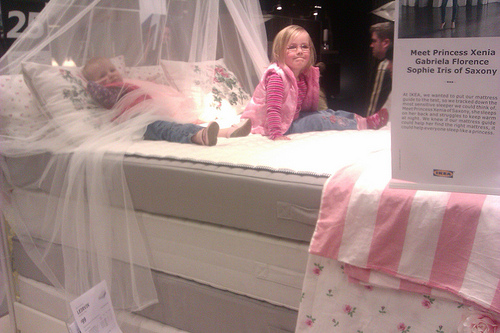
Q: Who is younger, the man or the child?
A: The child is younger than the man.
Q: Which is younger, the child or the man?
A: The child is younger than the man.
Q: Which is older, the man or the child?
A: The man is older than the child.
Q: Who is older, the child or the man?
A: The man is older than the child.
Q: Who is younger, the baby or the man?
A: The baby is younger than the man.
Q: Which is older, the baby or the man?
A: The man is older than the baby.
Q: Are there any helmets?
A: No, there are no helmets.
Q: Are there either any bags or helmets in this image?
A: No, there are no helmets or bags.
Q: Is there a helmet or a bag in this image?
A: No, there are no helmets or bags.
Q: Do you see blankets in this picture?
A: Yes, there is a blanket.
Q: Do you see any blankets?
A: Yes, there is a blanket.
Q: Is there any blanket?
A: Yes, there is a blanket.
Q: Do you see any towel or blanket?
A: Yes, there is a blanket.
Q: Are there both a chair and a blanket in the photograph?
A: No, there is a blanket but no chairs.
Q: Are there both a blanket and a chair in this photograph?
A: No, there is a blanket but no chairs.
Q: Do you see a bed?
A: Yes, there is a bed.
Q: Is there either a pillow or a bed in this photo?
A: Yes, there is a bed.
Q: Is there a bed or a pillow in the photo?
A: Yes, there is a bed.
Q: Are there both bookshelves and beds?
A: No, there is a bed but no bookshelves.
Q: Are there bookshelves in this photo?
A: No, there are no bookshelves.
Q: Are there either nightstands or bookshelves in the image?
A: No, there are no bookshelves or nightstands.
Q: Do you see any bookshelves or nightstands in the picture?
A: No, there are no bookshelves or nightstands.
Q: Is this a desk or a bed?
A: This is a bed.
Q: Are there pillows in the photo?
A: Yes, there is a pillow.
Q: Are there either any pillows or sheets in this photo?
A: Yes, there is a pillow.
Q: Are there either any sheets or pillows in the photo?
A: Yes, there is a pillow.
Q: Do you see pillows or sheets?
A: Yes, there is a pillow.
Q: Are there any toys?
A: No, there are no toys.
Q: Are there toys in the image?
A: No, there are no toys.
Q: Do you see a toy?
A: No, there are no toys.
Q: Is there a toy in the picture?
A: No, there are no toys.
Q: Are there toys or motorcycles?
A: No, there are no toys or motorcycles.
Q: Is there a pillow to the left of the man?
A: Yes, there is a pillow to the left of the man.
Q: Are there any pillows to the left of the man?
A: Yes, there is a pillow to the left of the man.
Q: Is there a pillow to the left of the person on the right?
A: Yes, there is a pillow to the left of the man.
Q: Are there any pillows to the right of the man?
A: No, the pillow is to the left of the man.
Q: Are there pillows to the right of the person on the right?
A: No, the pillow is to the left of the man.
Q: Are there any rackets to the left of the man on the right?
A: No, there is a pillow to the left of the man.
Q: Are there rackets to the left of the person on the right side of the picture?
A: No, there is a pillow to the left of the man.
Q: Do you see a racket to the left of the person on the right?
A: No, there is a pillow to the left of the man.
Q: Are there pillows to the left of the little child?
A: Yes, there is a pillow to the left of the child.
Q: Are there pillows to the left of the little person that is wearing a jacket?
A: Yes, there is a pillow to the left of the child.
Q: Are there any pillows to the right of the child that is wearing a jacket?
A: No, the pillow is to the left of the kid.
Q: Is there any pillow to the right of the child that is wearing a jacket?
A: No, the pillow is to the left of the kid.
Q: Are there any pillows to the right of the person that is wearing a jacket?
A: No, the pillow is to the left of the kid.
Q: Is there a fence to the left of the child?
A: No, there is a pillow to the left of the child.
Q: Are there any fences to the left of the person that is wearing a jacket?
A: No, there is a pillow to the left of the child.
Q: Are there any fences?
A: No, there are no fences.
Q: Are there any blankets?
A: Yes, there is a blanket.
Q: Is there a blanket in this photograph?
A: Yes, there is a blanket.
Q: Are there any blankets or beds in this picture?
A: Yes, there is a blanket.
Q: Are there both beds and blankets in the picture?
A: Yes, there are both a blanket and a bed.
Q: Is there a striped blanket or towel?
A: Yes, there is a striped blanket.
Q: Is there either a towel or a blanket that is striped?
A: Yes, the blanket is striped.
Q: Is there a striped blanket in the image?
A: Yes, there is a striped blanket.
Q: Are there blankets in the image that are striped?
A: Yes, there is a blanket that is striped.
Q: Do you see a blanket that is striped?
A: Yes, there is a blanket that is striped.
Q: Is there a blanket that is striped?
A: Yes, there is a blanket that is striped.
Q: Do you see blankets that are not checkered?
A: Yes, there is a striped blanket.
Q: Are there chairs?
A: No, there are no chairs.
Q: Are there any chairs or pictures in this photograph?
A: No, there are no chairs or pictures.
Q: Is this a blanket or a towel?
A: This is a blanket.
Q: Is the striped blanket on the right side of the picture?
A: Yes, the blanket is on the right of the image.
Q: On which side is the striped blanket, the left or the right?
A: The blanket is on the right of the image.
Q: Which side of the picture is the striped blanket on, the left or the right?
A: The blanket is on the right of the image.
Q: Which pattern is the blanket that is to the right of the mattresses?
A: The blanket is striped.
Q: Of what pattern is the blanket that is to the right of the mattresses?
A: The blanket is striped.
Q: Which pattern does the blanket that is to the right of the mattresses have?
A: The blanket has striped pattern.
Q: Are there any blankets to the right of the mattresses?
A: Yes, there is a blanket to the right of the mattresses.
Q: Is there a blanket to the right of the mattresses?
A: Yes, there is a blanket to the right of the mattresses.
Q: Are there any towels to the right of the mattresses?
A: No, there is a blanket to the right of the mattresses.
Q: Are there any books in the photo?
A: No, there are no books.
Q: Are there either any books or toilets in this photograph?
A: No, there are no books or toilets.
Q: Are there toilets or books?
A: No, there are no books or toilets.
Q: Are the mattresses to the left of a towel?
A: No, the mattresses are to the left of the blanket.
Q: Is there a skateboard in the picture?
A: No, there are no skateboards.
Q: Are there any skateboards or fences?
A: No, there are no skateboards or fences.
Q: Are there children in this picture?
A: Yes, there is a child.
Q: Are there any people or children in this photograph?
A: Yes, there is a child.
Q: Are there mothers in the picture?
A: No, there are no mothers.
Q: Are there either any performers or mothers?
A: No, there are no mothers or performers.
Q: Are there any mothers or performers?
A: No, there are no mothers or performers.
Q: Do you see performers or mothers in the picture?
A: No, there are no mothers or performers.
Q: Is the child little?
A: Yes, the child is little.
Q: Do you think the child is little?
A: Yes, the child is little.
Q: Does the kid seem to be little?
A: Yes, the kid is little.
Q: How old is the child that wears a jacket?
A: The child is little.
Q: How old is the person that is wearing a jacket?
A: The child is little.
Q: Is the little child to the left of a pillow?
A: No, the child is to the right of a pillow.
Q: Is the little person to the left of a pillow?
A: No, the child is to the right of a pillow.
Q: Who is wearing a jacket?
A: The child is wearing a jacket.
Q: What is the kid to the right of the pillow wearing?
A: The kid is wearing a jacket.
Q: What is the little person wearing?
A: The kid is wearing a jacket.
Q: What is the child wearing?
A: The kid is wearing a jacket.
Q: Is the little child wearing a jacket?
A: Yes, the child is wearing a jacket.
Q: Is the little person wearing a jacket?
A: Yes, the child is wearing a jacket.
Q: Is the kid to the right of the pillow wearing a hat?
A: No, the child is wearing a jacket.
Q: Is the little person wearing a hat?
A: No, the child is wearing a jacket.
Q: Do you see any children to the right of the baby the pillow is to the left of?
A: Yes, there is a child to the right of the baby.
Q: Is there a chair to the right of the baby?
A: No, there is a child to the right of the baby.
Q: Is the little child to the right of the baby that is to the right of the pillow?
A: Yes, the kid is to the right of the baby.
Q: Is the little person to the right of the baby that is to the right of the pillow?
A: Yes, the kid is to the right of the baby.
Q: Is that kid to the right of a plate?
A: No, the kid is to the right of the baby.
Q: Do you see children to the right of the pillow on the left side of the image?
A: Yes, there is a child to the right of the pillow.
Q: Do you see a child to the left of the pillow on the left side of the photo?
A: No, the child is to the right of the pillow.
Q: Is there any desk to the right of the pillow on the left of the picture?
A: No, there is a child to the right of the pillow.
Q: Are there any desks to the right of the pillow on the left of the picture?
A: No, there is a child to the right of the pillow.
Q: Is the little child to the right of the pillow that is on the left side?
A: Yes, the child is to the right of the pillow.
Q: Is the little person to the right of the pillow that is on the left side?
A: Yes, the child is to the right of the pillow.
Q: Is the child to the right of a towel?
A: No, the child is to the right of the pillow.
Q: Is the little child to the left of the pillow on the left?
A: No, the child is to the right of the pillow.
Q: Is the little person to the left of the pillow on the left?
A: No, the child is to the right of the pillow.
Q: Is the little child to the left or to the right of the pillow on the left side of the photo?
A: The child is to the right of the pillow.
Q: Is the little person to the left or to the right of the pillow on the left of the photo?
A: The child is to the right of the pillow.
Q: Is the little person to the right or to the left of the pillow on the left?
A: The child is to the right of the pillow.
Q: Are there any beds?
A: Yes, there is a bed.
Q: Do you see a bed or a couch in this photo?
A: Yes, there is a bed.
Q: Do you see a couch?
A: No, there are no couches.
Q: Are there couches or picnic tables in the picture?
A: No, there are no couches or picnic tables.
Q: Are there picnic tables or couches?
A: No, there are no couches or picnic tables.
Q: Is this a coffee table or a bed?
A: This is a bed.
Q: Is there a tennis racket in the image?
A: No, there are no rackets.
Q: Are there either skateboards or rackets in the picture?
A: No, there are no rackets or skateboards.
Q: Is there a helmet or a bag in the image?
A: No, there are no helmets or bags.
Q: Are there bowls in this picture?
A: No, there are no bowls.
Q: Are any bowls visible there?
A: No, there are no bowls.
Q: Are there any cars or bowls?
A: No, there are no bowls or cars.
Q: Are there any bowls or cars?
A: No, there are no bowls or cars.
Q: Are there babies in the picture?
A: Yes, there is a baby.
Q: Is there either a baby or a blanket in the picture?
A: Yes, there is a baby.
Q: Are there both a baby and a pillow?
A: Yes, there are both a baby and a pillow.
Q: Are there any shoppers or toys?
A: No, there are no toys or shoppers.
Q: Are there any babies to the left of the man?
A: Yes, there is a baby to the left of the man.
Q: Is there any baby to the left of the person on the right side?
A: Yes, there is a baby to the left of the man.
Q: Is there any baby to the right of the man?
A: No, the baby is to the left of the man.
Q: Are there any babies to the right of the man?
A: No, the baby is to the left of the man.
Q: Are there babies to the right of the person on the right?
A: No, the baby is to the left of the man.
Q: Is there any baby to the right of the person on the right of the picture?
A: No, the baby is to the left of the man.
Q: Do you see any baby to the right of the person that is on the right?
A: No, the baby is to the left of the man.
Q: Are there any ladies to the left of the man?
A: No, there is a baby to the left of the man.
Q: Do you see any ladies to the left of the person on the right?
A: No, there is a baby to the left of the man.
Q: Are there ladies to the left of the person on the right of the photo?
A: No, there is a baby to the left of the man.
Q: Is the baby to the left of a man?
A: Yes, the baby is to the left of a man.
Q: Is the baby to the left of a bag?
A: No, the baby is to the left of a man.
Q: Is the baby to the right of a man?
A: No, the baby is to the left of a man.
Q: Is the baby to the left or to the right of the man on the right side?
A: The baby is to the left of the man.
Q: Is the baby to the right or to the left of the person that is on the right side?
A: The baby is to the left of the man.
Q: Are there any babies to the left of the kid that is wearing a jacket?
A: Yes, there is a baby to the left of the child.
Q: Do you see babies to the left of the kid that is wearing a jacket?
A: Yes, there is a baby to the left of the child.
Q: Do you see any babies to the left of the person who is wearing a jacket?
A: Yes, there is a baby to the left of the child.